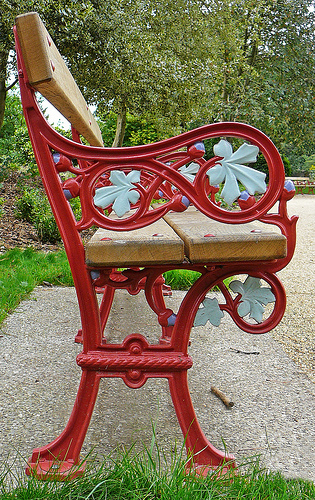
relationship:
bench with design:
[7, 11, 300, 482] [205, 136, 268, 205]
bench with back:
[7, 11, 300, 482] [19, 15, 99, 131]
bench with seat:
[7, 11, 300, 482] [86, 224, 292, 263]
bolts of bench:
[85, 204, 287, 266] [7, 11, 300, 482]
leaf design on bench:
[190, 272, 278, 329] [7, 11, 300, 482]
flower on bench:
[168, 194, 189, 212] [7, 9, 313, 410]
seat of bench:
[87, 200, 290, 270] [7, 11, 300, 482]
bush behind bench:
[13, 191, 51, 238] [21, 8, 288, 476]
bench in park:
[7, 11, 300, 482] [1, 0, 311, 498]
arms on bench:
[36, 104, 297, 236] [33, 22, 160, 185]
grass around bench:
[4, 250, 63, 291] [13, 11, 299, 487]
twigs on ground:
[208, 381, 239, 410] [0, 176, 311, 498]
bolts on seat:
[84, 220, 242, 254] [66, 130, 273, 301]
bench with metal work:
[7, 11, 300, 482] [9, 26, 297, 479]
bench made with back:
[7, 11, 300, 482] [14, 12, 104, 147]